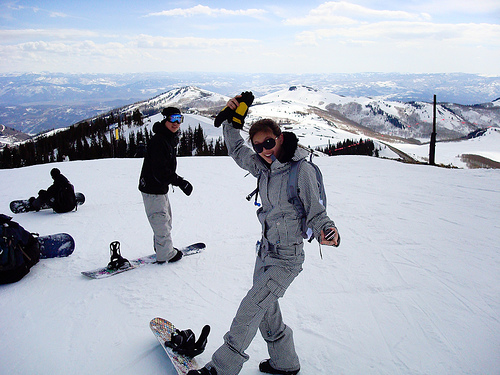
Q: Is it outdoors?
A: Yes, it is outdoors.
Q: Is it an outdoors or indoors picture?
A: It is outdoors.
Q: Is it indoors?
A: No, it is outdoors.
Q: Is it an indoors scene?
A: No, it is outdoors.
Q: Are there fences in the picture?
A: No, there are no fences.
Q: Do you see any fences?
A: No, there are no fences.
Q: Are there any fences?
A: No, there are no fences.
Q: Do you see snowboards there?
A: Yes, there is a snowboard.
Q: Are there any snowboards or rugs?
A: Yes, there is a snowboard.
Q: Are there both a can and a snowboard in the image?
A: No, there is a snowboard but no cans.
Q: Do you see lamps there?
A: No, there are no lamps.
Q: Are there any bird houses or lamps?
A: No, there are no lamps or bird houses.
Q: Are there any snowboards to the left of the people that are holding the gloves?
A: Yes, there is a snowboard to the left of the people.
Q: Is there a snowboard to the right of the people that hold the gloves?
A: No, the snowboard is to the left of the people.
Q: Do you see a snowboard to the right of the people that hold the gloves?
A: No, the snowboard is to the left of the people.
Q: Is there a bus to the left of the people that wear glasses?
A: No, there is a snowboard to the left of the people.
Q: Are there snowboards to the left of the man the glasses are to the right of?
A: Yes, there is a snowboard to the left of the man.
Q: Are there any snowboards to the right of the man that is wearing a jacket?
A: No, the snowboard is to the left of the man.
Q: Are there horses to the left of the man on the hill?
A: No, there is a snowboard to the left of the man.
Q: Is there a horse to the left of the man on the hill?
A: No, there is a snowboard to the left of the man.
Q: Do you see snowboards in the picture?
A: Yes, there is a snowboard.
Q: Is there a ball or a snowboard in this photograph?
A: Yes, there is a snowboard.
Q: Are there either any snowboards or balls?
A: Yes, there is a snowboard.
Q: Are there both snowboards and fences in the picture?
A: No, there is a snowboard but no fences.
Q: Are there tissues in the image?
A: No, there are no tissues.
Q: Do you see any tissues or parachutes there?
A: No, there are no tissues or parachutes.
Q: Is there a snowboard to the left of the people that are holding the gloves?
A: Yes, there is a snowboard to the left of the people.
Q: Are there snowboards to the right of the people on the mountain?
A: No, the snowboard is to the left of the people.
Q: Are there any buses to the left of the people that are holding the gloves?
A: No, there is a snowboard to the left of the people.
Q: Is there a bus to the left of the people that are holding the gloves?
A: No, there is a snowboard to the left of the people.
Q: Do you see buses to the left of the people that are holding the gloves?
A: No, there is a snowboard to the left of the people.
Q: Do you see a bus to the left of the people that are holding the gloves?
A: No, there is a snowboard to the left of the people.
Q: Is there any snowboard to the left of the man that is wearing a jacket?
A: Yes, there is a snowboard to the left of the man.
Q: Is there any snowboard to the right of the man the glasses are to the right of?
A: No, the snowboard is to the left of the man.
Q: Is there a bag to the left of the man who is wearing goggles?
A: No, there is a snowboard to the left of the man.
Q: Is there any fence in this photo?
A: No, there are no fences.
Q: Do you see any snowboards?
A: Yes, there is a snowboard.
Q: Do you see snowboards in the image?
A: Yes, there is a snowboard.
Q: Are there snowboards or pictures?
A: Yes, there is a snowboard.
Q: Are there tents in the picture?
A: No, there are no tents.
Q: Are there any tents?
A: No, there are no tents.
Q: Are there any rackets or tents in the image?
A: No, there are no tents or rackets.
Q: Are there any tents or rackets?
A: No, there are no tents or rackets.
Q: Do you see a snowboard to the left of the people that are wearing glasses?
A: Yes, there is a snowboard to the left of the people.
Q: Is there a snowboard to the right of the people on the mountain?
A: No, the snowboard is to the left of the people.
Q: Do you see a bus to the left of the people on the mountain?
A: No, there is a snowboard to the left of the people.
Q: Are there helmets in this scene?
A: No, there are no helmets.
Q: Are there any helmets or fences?
A: No, there are no helmets or fences.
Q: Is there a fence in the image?
A: No, there are no fences.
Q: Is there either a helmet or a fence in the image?
A: No, there are no fences or helmets.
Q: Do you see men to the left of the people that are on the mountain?
A: Yes, there is a man to the left of the people.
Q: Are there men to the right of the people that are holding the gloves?
A: No, the man is to the left of the people.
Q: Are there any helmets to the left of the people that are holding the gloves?
A: No, there is a man to the left of the people.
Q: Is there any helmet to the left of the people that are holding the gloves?
A: No, there is a man to the left of the people.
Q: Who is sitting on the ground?
A: The man is sitting on the ground.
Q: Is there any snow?
A: Yes, there is snow.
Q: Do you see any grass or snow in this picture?
A: Yes, there is snow.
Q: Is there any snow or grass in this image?
A: Yes, there is snow.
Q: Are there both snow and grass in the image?
A: No, there is snow but no grass.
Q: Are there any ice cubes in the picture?
A: No, there are no ice cubes.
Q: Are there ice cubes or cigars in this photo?
A: No, there are no ice cubes or cigars.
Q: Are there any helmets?
A: No, there are no helmets.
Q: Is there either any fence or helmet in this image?
A: No, there are no helmets or fences.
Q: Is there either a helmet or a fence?
A: No, there are no helmets or fences.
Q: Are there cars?
A: No, there are no cars.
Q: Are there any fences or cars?
A: No, there are no cars or fences.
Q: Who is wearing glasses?
A: The people are wearing glasses.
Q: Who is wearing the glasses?
A: The people are wearing glasses.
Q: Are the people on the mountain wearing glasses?
A: Yes, the people are wearing glasses.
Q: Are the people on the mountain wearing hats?
A: No, the people are wearing glasses.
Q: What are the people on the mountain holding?
A: The people are holding the gloves.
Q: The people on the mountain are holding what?
A: The people are holding the gloves.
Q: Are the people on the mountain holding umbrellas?
A: No, the people are holding the gloves.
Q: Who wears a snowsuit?
A: The people wear a snowsuit.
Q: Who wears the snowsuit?
A: The people wear a snowsuit.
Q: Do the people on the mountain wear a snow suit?
A: Yes, the people wear a snow suit.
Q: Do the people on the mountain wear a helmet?
A: No, the people wear a snow suit.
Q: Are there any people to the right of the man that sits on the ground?
A: Yes, there are people to the right of the man.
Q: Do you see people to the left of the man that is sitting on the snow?
A: No, the people are to the right of the man.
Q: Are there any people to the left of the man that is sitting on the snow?
A: No, the people are to the right of the man.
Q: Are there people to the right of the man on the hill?
A: Yes, there are people to the right of the man.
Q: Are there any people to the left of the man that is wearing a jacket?
A: No, the people are to the right of the man.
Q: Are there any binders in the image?
A: No, there are no binders.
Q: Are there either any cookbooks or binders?
A: No, there are no binders or cookbooks.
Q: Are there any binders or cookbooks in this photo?
A: No, there are no binders or cookbooks.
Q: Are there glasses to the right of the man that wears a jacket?
A: Yes, there are glasses to the right of the man.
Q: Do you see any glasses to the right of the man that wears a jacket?
A: Yes, there are glasses to the right of the man.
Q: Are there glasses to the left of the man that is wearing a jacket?
A: No, the glasses are to the right of the man.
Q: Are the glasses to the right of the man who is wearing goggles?
A: Yes, the glasses are to the right of the man.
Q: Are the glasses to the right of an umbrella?
A: No, the glasses are to the right of the man.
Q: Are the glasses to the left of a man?
A: No, the glasses are to the right of a man.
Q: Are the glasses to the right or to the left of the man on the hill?
A: The glasses are to the right of the man.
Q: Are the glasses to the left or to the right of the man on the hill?
A: The glasses are to the right of the man.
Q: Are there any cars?
A: No, there are no cars.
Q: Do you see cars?
A: No, there are no cars.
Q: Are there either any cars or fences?
A: No, there are no cars or fences.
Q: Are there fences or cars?
A: No, there are no cars or fences.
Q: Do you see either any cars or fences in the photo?
A: No, there are no cars or fences.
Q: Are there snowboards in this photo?
A: Yes, there is a snowboard.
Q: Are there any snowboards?
A: Yes, there is a snowboard.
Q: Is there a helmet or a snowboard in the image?
A: Yes, there is a snowboard.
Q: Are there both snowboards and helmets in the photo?
A: No, there is a snowboard but no helmets.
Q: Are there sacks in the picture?
A: No, there are no sacks.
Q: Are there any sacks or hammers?
A: No, there are no sacks or hammers.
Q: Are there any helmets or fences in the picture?
A: No, there are no helmets or fences.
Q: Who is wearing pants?
A: The man is wearing pants.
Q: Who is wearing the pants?
A: The man is wearing pants.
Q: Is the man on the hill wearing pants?
A: Yes, the man is wearing pants.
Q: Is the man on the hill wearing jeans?
A: No, the man is wearing pants.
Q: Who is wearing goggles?
A: The man is wearing goggles.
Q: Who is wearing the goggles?
A: The man is wearing goggles.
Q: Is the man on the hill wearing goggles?
A: Yes, the man is wearing goggles.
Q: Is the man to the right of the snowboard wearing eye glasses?
A: No, the man is wearing goggles.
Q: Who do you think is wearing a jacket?
A: The man is wearing a jacket.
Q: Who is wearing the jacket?
A: The man is wearing a jacket.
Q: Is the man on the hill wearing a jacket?
A: Yes, the man is wearing a jacket.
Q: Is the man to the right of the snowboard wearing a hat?
A: No, the man is wearing a jacket.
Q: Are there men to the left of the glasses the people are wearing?
A: Yes, there is a man to the left of the glasses.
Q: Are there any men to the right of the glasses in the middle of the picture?
A: No, the man is to the left of the glasses.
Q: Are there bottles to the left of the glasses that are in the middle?
A: No, there is a man to the left of the glasses.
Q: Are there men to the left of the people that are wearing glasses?
A: Yes, there is a man to the left of the people.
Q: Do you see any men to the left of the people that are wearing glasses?
A: Yes, there is a man to the left of the people.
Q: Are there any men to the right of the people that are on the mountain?
A: No, the man is to the left of the people.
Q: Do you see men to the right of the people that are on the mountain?
A: No, the man is to the left of the people.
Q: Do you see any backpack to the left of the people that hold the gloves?
A: No, there is a man to the left of the people.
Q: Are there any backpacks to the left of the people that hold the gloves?
A: No, there is a man to the left of the people.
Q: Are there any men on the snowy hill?
A: Yes, there is a man on the hill.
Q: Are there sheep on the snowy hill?
A: No, there is a man on the hill.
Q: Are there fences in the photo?
A: No, there are no fences.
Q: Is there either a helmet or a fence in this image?
A: No, there are no fences or helmets.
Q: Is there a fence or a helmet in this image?
A: No, there are no fences or helmets.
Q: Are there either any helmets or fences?
A: No, there are no fences or helmets.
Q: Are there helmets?
A: No, there are no helmets.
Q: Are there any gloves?
A: Yes, there are gloves.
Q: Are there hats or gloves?
A: Yes, there are gloves.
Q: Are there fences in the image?
A: No, there are no fences.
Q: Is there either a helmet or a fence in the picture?
A: No, there are no fences or helmets.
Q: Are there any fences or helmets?
A: No, there are no fences or helmets.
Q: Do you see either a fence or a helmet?
A: No, there are no fences or helmets.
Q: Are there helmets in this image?
A: No, there are no helmets.